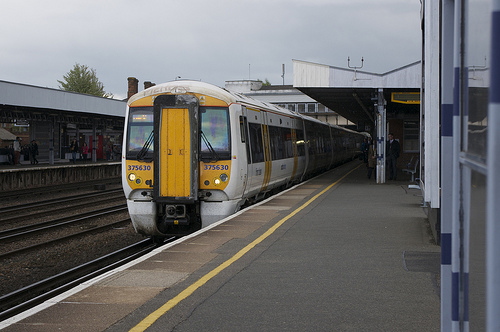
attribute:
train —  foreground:
[104, 63, 344, 222]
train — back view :
[104, 72, 375, 230]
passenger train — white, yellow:
[120, 77, 373, 247]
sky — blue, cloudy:
[1, 1, 424, 111]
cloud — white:
[107, 92, 122, 103]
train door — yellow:
[157, 105, 190, 199]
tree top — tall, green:
[56, 62, 117, 106]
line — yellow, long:
[126, 156, 368, 326]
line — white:
[0, 169, 306, 329]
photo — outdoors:
[1, 2, 499, 328]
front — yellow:
[126, 88, 238, 203]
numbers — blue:
[200, 162, 231, 173]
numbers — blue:
[128, 164, 157, 172]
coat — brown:
[366, 142, 378, 170]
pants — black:
[367, 167, 378, 178]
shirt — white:
[372, 143, 376, 155]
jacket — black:
[383, 138, 401, 163]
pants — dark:
[385, 154, 397, 180]